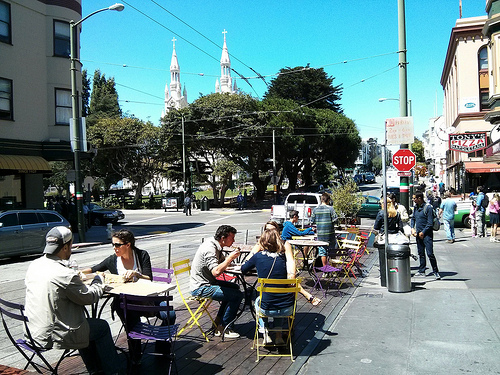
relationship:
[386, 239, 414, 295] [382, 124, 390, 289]
can near post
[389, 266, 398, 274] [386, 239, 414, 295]
sticker on top of can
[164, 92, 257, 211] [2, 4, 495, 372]
tree inside city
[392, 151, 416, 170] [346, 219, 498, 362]
sign on top of street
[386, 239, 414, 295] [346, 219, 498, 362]
receptacle on top of street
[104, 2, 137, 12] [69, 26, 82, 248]
light on top of post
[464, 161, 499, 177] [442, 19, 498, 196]
awning on top of building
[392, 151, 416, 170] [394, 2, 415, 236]
sign on top of pole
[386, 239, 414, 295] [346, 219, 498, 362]
can on top of sidewalk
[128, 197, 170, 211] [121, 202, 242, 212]
bench on top of sidewalk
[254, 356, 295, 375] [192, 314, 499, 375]
bricks on sidewalk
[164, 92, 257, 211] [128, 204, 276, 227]
trees near street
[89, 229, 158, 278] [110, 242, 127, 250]
woman has sunglasses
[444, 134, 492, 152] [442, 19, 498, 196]
sign for place